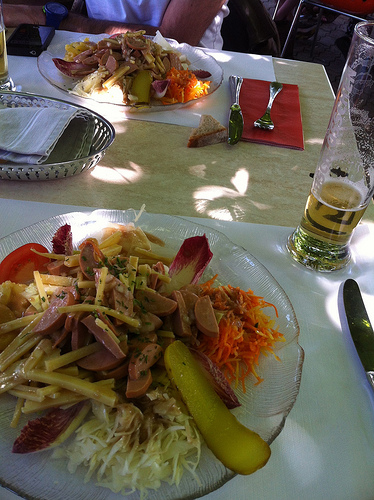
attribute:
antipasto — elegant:
[1, 207, 306, 500]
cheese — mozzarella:
[72, 402, 206, 491]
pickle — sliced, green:
[162, 337, 274, 476]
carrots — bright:
[159, 67, 284, 394]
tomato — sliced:
[0, 241, 53, 283]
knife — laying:
[342, 277, 374, 389]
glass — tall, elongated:
[287, 17, 374, 275]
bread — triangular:
[188, 114, 230, 147]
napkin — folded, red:
[231, 77, 304, 150]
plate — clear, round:
[38, 34, 225, 110]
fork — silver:
[253, 78, 284, 131]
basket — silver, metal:
[0, 90, 116, 181]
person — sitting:
[0, 0, 228, 51]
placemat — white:
[1, 199, 374, 500]